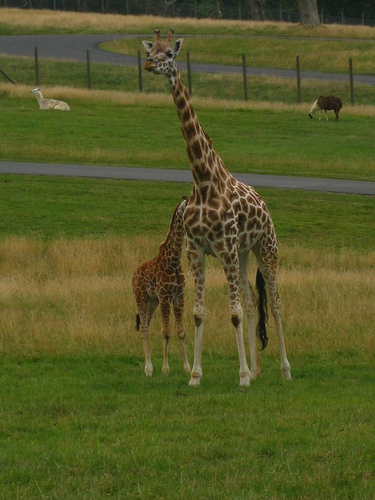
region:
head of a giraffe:
[137, 28, 181, 75]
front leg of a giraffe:
[183, 209, 207, 385]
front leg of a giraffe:
[210, 215, 252, 384]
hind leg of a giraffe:
[252, 228, 293, 379]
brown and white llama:
[306, 93, 343, 124]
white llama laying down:
[28, 85, 68, 112]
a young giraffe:
[131, 196, 193, 373]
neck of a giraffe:
[165, 70, 226, 185]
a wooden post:
[32, 46, 40, 84]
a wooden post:
[241, 54, 248, 101]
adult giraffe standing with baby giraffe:
[117, 24, 302, 382]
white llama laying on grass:
[24, 84, 69, 112]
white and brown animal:
[303, 89, 349, 123]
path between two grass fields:
[7, 153, 363, 199]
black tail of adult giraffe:
[247, 267, 274, 344]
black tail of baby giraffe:
[130, 307, 144, 328]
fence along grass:
[4, 37, 373, 109]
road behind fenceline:
[16, 17, 366, 94]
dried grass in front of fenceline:
[5, 86, 374, 119]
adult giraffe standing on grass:
[138, 30, 297, 388]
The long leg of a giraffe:
[193, 259, 202, 379]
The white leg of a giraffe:
[194, 331, 199, 372]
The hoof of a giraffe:
[238, 368, 249, 385]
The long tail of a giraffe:
[258, 276, 264, 344]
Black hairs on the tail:
[134, 315, 139, 330]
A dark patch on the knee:
[232, 315, 237, 325]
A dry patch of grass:
[39, 281, 119, 305]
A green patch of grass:
[17, 390, 117, 416]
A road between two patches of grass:
[84, 166, 133, 174]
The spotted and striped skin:
[201, 184, 233, 228]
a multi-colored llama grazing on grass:
[294, 84, 348, 130]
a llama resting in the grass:
[28, 84, 88, 118]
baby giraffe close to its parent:
[103, 167, 213, 383]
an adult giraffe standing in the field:
[123, 28, 300, 363]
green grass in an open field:
[27, 386, 355, 493]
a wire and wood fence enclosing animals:
[8, 45, 367, 130]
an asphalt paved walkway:
[19, 154, 367, 208]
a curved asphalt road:
[4, 9, 365, 100]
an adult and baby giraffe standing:
[94, 35, 310, 375]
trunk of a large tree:
[297, 2, 335, 31]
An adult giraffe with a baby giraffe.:
[130, 26, 293, 387]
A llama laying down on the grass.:
[27, 86, 72, 111]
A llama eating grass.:
[308, 95, 343, 120]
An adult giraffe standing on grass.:
[143, 26, 291, 386]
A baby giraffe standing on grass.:
[130, 197, 202, 375]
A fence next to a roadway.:
[2, 47, 374, 106]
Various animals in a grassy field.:
[1, 6, 370, 495]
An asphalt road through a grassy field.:
[1, 158, 373, 195]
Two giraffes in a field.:
[129, 28, 295, 388]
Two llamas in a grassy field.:
[30, 86, 342, 122]